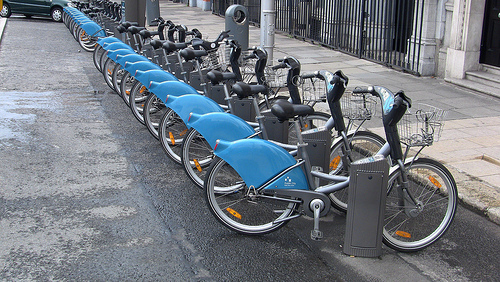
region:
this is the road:
[52, 171, 204, 248]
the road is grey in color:
[46, 208, 167, 274]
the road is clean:
[70, 161, 142, 273]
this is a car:
[6, 2, 66, 17]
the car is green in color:
[27, 3, 48, 15]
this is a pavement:
[448, 97, 478, 145]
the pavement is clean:
[445, 102, 487, 138]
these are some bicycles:
[92, 10, 459, 249]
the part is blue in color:
[247, 151, 269, 179]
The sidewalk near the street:
[153, 0, 498, 218]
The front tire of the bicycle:
[381, 155, 455, 251]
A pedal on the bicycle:
[308, 202, 325, 241]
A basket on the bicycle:
[399, 102, 442, 144]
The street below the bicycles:
[0, 17, 497, 279]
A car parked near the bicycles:
[0, 0, 65, 22]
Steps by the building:
[444, 64, 498, 99]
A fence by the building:
[206, 0, 423, 75]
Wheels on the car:
[1, 5, 61, 20]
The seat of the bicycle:
[274, 99, 312, 119]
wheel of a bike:
[360, 144, 477, 262]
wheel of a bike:
[205, 130, 300, 238]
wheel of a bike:
[170, 100, 241, 182]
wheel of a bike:
[146, 81, 208, 163]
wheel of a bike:
[137, 78, 173, 140]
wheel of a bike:
[126, 62, 171, 129]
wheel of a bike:
[118, 56, 153, 103]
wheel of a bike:
[103, 42, 142, 110]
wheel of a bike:
[91, 32, 125, 80]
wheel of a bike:
[72, 22, 109, 49]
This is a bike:
[203, 84, 479, 267]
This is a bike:
[180, 61, 395, 178]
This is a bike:
[128, 46, 310, 173]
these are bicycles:
[64, 19, 450, 249]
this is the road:
[34, 197, 188, 272]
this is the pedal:
[308, 213, 323, 241]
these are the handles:
[350, 82, 400, 117]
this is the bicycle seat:
[273, 100, 313, 121]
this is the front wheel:
[378, 168, 452, 238]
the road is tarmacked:
[8, 102, 124, 259]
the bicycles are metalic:
[143, 54, 388, 229]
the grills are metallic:
[289, 5, 396, 41]